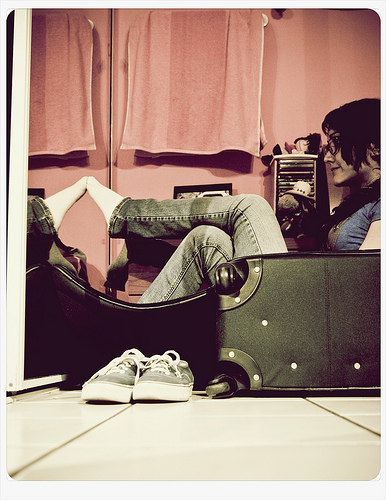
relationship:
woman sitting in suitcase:
[90, 89, 383, 293] [208, 248, 385, 396]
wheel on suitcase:
[201, 366, 242, 401] [208, 248, 385, 396]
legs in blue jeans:
[84, 171, 287, 304] [105, 196, 287, 303]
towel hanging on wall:
[118, 14, 273, 158] [113, 11, 322, 193]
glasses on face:
[318, 138, 344, 156] [321, 131, 353, 190]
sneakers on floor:
[75, 345, 202, 407] [15, 406, 381, 490]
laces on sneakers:
[90, 342, 188, 375] [75, 345, 202, 407]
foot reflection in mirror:
[42, 177, 89, 227] [15, 12, 121, 288]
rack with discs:
[274, 153, 324, 244] [276, 160, 312, 228]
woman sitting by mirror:
[90, 89, 383, 293] [15, 12, 121, 288]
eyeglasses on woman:
[318, 138, 344, 156] [90, 89, 383, 293]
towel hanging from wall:
[118, 14, 273, 158] [113, 11, 322, 193]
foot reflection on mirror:
[42, 177, 89, 227] [15, 12, 121, 288]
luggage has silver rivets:
[208, 248, 385, 396] [285, 357, 366, 374]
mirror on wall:
[15, 12, 121, 288] [12, 12, 297, 187]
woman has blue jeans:
[90, 89, 383, 293] [105, 196, 287, 303]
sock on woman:
[82, 174, 125, 228] [90, 89, 383, 293]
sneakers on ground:
[75, 345, 202, 407] [15, 406, 381, 490]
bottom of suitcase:
[209, 366, 380, 394] [208, 248, 385, 396]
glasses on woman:
[318, 138, 344, 156] [90, 89, 383, 293]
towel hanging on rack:
[118, 14, 273, 158] [111, 11, 275, 29]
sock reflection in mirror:
[82, 174, 125, 228] [15, 12, 121, 288]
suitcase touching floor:
[208, 248, 385, 396] [15, 406, 381, 490]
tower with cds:
[274, 153, 324, 244] [276, 160, 312, 228]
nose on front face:
[321, 150, 338, 167] [321, 131, 353, 190]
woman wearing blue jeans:
[90, 89, 383, 293] [84, 171, 287, 304]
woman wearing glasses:
[90, 89, 383, 293] [318, 138, 344, 156]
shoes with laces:
[75, 345, 202, 407] [90, 342, 188, 375]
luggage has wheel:
[208, 248, 385, 396] [201, 366, 234, 403]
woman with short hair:
[90, 89, 383, 293] [317, 96, 385, 189]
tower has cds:
[274, 153, 324, 244] [276, 160, 312, 228]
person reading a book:
[90, 89, 383, 293] [263, 148, 325, 229]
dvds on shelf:
[274, 153, 324, 244] [269, 148, 333, 245]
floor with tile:
[15, 406, 381, 490] [81, 400, 266, 452]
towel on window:
[118, 14, 273, 158] [129, 29, 265, 151]